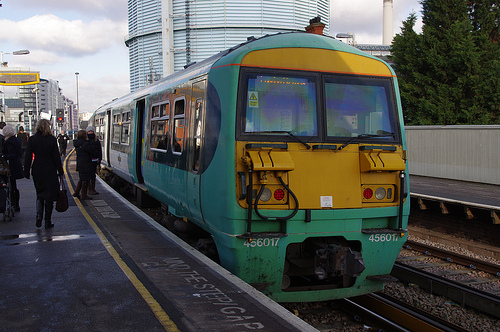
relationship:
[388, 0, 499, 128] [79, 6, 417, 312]
tree behind train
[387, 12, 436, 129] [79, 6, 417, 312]
tree behind train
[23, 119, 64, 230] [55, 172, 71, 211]
people carrying bag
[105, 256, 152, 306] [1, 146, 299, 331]
markings on sidewalk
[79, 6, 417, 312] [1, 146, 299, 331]
train near sidewalk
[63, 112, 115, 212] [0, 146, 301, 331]
person standing on ground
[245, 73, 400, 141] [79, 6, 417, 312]
glass on train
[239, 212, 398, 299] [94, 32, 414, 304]
bumper on train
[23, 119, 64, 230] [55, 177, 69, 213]
people holding bag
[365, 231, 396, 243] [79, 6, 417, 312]
number on train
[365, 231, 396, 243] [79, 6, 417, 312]
number of train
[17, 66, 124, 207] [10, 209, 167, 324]
people standing on platform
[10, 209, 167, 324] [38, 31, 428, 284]
platform near train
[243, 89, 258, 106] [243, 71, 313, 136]
sticker on window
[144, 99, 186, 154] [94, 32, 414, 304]
windows on side of train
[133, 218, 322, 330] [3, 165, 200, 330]
white line on sidewalk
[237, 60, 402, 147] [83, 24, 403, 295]
glass on front of train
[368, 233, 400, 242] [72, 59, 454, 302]
number on train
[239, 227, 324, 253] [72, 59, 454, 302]
numbers on train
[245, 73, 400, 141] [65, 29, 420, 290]
glass on train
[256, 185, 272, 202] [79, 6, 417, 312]
headlight on train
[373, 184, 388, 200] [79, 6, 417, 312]
headlight on train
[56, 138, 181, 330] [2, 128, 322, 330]
line on sidewalk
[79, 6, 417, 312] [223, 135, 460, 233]
train signal light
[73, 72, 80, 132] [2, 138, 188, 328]
lamp post on street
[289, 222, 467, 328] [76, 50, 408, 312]
train tracks under train